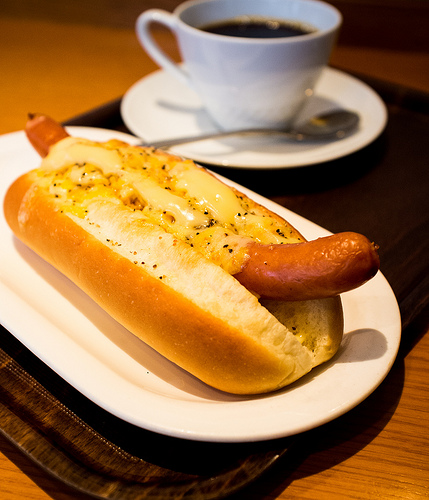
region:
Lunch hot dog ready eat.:
[7, 99, 390, 396]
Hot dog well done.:
[194, 205, 382, 292]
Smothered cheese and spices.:
[106, 155, 378, 297]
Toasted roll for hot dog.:
[17, 155, 240, 314]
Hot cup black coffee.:
[138, 2, 350, 112]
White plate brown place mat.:
[1, 375, 289, 498]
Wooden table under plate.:
[338, 295, 422, 497]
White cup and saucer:
[140, 4, 372, 170]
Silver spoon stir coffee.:
[144, 99, 370, 160]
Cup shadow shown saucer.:
[142, 79, 352, 133]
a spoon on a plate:
[132, 104, 362, 155]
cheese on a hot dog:
[32, 134, 302, 273]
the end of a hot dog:
[230, 229, 387, 304]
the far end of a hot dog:
[22, 110, 71, 159]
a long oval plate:
[0, 125, 403, 441]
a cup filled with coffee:
[133, 0, 343, 133]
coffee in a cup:
[193, 15, 320, 38]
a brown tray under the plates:
[0, 60, 428, 498]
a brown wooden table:
[0, 1, 427, 498]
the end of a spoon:
[287, 105, 360, 142]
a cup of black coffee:
[99, 5, 388, 169]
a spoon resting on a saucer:
[139, 109, 363, 156]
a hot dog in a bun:
[5, 113, 393, 387]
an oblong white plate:
[2, 117, 405, 454]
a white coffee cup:
[135, 7, 345, 137]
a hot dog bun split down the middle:
[9, 174, 366, 386]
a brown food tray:
[15, 383, 250, 496]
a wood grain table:
[324, 445, 411, 492]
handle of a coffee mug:
[134, 6, 197, 109]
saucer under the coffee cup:
[118, 78, 397, 168]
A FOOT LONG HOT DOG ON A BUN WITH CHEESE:
[1, 109, 378, 401]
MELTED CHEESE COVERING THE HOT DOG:
[44, 126, 285, 273]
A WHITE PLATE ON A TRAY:
[5, 115, 402, 448]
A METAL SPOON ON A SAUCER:
[132, 99, 358, 158]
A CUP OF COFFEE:
[119, 0, 350, 135]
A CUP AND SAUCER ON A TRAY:
[103, 1, 389, 184]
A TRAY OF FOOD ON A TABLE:
[0, 21, 428, 490]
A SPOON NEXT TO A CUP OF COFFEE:
[130, 96, 376, 161]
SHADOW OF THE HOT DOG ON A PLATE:
[343, 323, 393, 371]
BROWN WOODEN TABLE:
[358, 437, 422, 498]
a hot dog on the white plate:
[13, 109, 397, 436]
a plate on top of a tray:
[1, 154, 417, 478]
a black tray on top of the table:
[36, 411, 101, 460]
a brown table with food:
[363, 447, 418, 471]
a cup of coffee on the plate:
[140, 12, 396, 200]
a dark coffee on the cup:
[205, 4, 339, 61]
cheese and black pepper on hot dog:
[62, 129, 340, 341]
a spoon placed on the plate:
[146, 93, 400, 154]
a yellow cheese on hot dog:
[16, 163, 262, 252]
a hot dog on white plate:
[30, 137, 264, 464]